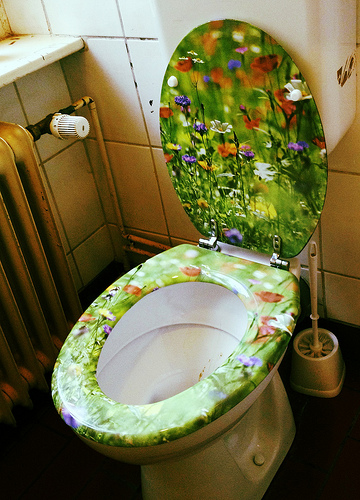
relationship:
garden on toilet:
[139, 34, 312, 281] [78, 89, 314, 499]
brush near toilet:
[298, 239, 337, 338] [78, 89, 314, 499]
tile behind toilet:
[93, 25, 177, 234] [78, 89, 314, 499]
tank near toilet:
[161, 7, 359, 155] [78, 89, 314, 499]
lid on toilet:
[165, 28, 325, 261] [78, 89, 314, 499]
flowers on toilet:
[173, 56, 293, 234] [78, 89, 314, 499]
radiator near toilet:
[10, 97, 76, 422] [78, 89, 314, 499]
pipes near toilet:
[73, 97, 167, 263] [78, 89, 314, 499]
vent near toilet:
[52, 111, 95, 151] [78, 89, 314, 499]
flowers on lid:
[173, 56, 293, 234] [165, 28, 325, 261]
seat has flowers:
[55, 231, 304, 434] [173, 56, 293, 234]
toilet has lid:
[78, 89, 314, 499] [165, 28, 325, 261]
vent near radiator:
[52, 111, 95, 151] [10, 97, 76, 422]